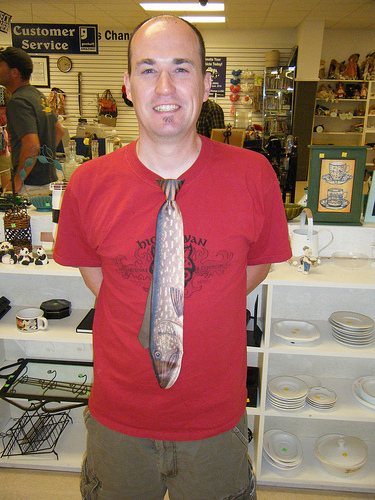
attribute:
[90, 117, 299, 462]
shirt — red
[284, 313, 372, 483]
ceramics — sold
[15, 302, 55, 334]
cup — sold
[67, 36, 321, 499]
man — bald, standing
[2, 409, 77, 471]
steamer — sold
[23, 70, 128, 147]
purses — sold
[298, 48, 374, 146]
dolls — sold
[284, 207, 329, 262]
watering can — sold, white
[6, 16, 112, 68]
sign — posted, hung, black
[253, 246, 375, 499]
shelves — white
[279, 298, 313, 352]
plate — white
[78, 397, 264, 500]
pants — grey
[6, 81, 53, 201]
shirt — grey